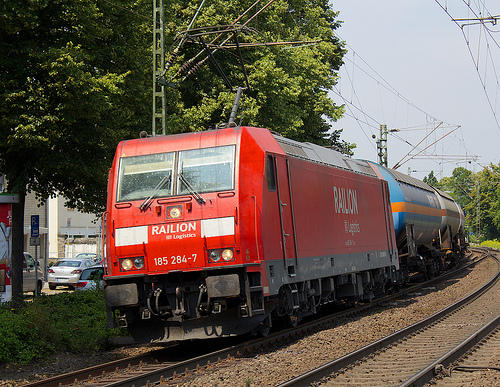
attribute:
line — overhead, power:
[432, 3, 498, 135]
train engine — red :
[90, 122, 400, 345]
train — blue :
[100, 123, 471, 349]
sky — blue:
[366, 5, 438, 62]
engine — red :
[123, 132, 455, 294]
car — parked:
[52, 243, 97, 296]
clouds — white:
[345, 24, 399, 71]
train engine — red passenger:
[108, 122, 398, 318]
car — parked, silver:
[40, 244, 117, 308]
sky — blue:
[322, 0, 498, 180]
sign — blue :
[28, 213, 39, 237]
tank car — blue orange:
[383, 164, 444, 256]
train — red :
[101, 127, 398, 344]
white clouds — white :
[468, 115, 487, 133]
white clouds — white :
[440, 84, 463, 108]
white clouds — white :
[405, 37, 440, 62]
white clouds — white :
[360, 90, 387, 105]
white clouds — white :
[373, 26, 395, 51]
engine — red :
[108, 127, 400, 323]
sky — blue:
[351, 29, 433, 107]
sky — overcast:
[332, 9, 497, 185]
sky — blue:
[338, 15, 438, 84]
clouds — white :
[355, 10, 498, 180]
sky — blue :
[317, 4, 498, 196]